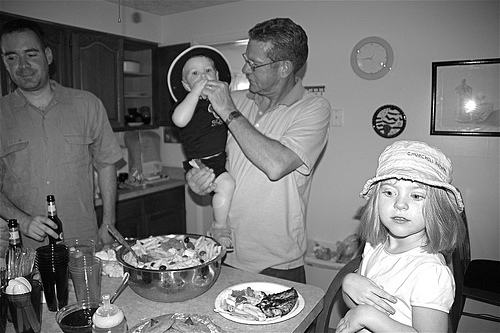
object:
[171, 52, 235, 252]
baby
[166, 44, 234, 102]
hat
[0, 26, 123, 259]
man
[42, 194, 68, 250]
beer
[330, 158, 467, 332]
girl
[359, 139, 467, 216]
hat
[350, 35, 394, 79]
clock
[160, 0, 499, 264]
wall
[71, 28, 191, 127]
cabinet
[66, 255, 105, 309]
cups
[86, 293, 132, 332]
bottle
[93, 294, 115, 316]
nipple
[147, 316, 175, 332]
cookies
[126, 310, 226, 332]
plate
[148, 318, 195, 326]
chocolate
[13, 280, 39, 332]
spoons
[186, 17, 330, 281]
man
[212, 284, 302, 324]
food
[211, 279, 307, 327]
plate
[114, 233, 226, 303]
bowl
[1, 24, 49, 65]
hair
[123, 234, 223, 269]
fruit salad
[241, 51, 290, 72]
glasses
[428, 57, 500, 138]
picture frame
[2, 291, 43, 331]
cup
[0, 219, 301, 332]
food and drinks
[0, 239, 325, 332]
counter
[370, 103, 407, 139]
picture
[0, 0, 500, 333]
kitchen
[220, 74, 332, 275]
shirt